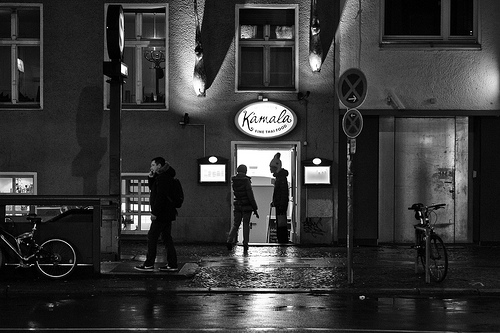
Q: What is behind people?
A: Restaurant.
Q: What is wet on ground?
A: Sidewalk.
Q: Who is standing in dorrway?
A: The woman.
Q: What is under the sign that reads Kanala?
A: A doorway.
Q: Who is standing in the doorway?
A: Two people.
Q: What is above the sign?
A: A window on the building.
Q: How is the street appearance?
A: Wet.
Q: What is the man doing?
A: Walking on the sidewalk.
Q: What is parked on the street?
A: A bicycle.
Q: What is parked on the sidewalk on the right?
A: A bicycle.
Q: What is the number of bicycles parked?
A: Two.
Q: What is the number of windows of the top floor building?
A: Three.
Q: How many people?
A: Three.